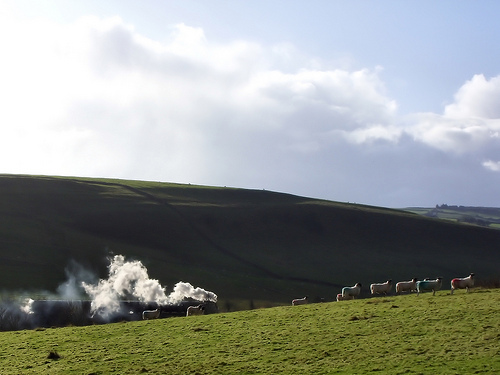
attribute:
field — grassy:
[2, 331, 497, 373]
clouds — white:
[4, 8, 498, 202]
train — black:
[18, 291, 215, 338]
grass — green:
[248, 329, 443, 366]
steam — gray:
[66, 251, 233, 338]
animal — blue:
[417, 277, 442, 296]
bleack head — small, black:
[352, 274, 366, 296]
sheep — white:
[338, 282, 365, 304]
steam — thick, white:
[84, 250, 223, 322]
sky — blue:
[378, 27, 485, 102]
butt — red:
[451, 276, 474, 291]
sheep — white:
[448, 272, 478, 296]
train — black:
[43, 272, 244, 364]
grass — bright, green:
[15, 291, 495, 373]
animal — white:
[287, 296, 308, 311]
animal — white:
[137, 299, 163, 323]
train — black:
[2, 303, 214, 331]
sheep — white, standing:
[183, 302, 204, 318]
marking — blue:
[419, 280, 430, 290]